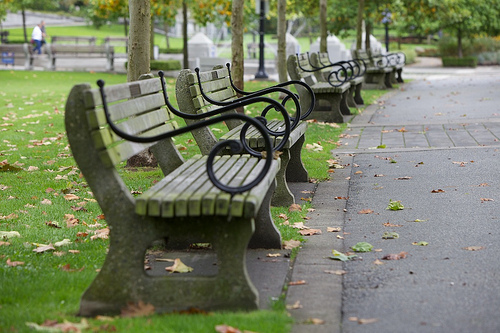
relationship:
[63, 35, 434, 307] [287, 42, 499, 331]
benches by a trail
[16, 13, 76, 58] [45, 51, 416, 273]
people walking through park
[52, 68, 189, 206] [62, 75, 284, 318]
backrest of a bench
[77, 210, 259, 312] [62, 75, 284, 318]
bottom base of bench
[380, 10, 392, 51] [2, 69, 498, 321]
lampost in park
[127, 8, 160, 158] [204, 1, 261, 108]
trunk part of tree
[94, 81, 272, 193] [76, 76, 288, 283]
arm of bench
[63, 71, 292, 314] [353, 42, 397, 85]
benches of park bench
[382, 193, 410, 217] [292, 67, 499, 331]
leaf on trail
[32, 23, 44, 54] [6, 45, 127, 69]
people on path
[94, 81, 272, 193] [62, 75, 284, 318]
arm on bench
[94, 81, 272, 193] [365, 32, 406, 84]
arm on bench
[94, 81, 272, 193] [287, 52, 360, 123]
arm on bench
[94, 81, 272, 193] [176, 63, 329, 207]
arm on bench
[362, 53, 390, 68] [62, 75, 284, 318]
arm rest on bench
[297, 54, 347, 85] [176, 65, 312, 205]
arm rest on bench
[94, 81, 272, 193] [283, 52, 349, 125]
arm on bench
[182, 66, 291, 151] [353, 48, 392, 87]
arm rest on bench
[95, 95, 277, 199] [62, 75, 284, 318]
rest on bench